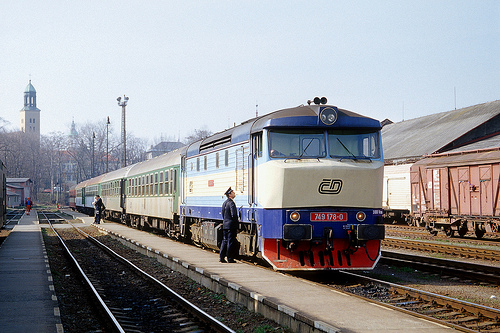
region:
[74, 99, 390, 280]
A train on tracks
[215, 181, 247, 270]
A railroad employee in blue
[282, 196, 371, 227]
The headlights of a train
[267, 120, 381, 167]
Clean windows of train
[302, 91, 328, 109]
The trains horn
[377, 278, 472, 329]
Rail road track of wood and steel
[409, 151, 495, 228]
A reddish train car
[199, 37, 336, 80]
Hazy blue sky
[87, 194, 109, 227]
A man in blue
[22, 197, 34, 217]
A pedestrian in blue and red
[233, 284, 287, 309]
white stripes on side of the track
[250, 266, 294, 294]
gray color on the platform track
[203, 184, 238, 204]
black cap on man's head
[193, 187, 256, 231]
man wearing blue jacket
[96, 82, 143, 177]
large silver light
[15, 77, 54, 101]
green dome on top of building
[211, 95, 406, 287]
blue red and white train on track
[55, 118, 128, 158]
tall trees in the background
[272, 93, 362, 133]
large light on top of train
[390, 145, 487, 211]
red train on the tracks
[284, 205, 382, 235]
headlights are on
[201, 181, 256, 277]
worker talking to conductor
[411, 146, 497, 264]
red train car next to train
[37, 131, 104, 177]
trees do not have leaves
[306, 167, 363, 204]
CD written on the front of train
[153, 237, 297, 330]
painted white lines on the cement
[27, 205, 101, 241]
walkway over the tracks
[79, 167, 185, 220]
train has a green stripe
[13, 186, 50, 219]
person walking on the sidewalk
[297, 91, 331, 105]
two horns on top of train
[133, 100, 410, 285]
blue and white train car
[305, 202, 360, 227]
red tag with white text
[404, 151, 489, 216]
dark red train car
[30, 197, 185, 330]
empty train track beside walkway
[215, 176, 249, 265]
man in uniform beside train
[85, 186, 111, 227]
person standing beside train car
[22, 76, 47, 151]
tall building behind trees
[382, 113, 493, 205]
white building with sloped roof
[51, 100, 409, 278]
train siting on middle track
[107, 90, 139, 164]
tall lamp post behind train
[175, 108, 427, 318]
front of train blue and white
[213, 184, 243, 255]
man is speaking to man on train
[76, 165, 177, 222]
part of grain is green and white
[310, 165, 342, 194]
black letters on train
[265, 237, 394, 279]
bottom part of train is red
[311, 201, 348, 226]
white lettering on sign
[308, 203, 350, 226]
red sign on train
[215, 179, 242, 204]
man wearing a hat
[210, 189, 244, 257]
man's clothes are black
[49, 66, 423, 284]
train is not in motion